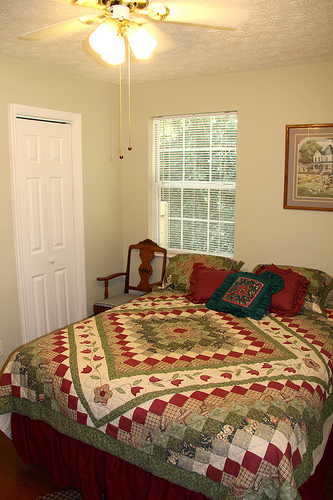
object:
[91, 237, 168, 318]
chair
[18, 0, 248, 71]
fan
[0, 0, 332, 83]
ceiling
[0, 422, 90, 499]
floor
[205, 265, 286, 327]
pillows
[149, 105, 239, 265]
window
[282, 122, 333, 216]
painting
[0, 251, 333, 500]
bed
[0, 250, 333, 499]
bedspread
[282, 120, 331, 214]
frame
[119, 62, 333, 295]
wall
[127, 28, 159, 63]
light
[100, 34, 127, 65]
light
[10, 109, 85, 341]
door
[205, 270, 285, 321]
cover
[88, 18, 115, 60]
lights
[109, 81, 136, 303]
corner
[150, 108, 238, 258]
sunlight